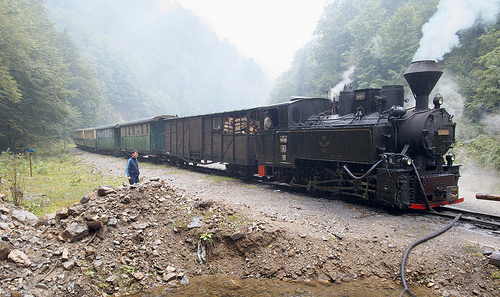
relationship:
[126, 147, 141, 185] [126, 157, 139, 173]
man wearing jacket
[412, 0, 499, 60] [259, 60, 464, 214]
steam coming from engine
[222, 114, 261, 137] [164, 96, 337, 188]
logs in car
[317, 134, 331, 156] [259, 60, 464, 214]
logo on engine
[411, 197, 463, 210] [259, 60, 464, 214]
bumper on engine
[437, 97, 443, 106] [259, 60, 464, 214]
light on engine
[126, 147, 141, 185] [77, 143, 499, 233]
man near tracks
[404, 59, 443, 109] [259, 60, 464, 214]
chimney on engine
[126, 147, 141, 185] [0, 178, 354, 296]
man near dirt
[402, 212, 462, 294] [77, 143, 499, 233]
hose coming from tracks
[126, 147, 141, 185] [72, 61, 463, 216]
man near train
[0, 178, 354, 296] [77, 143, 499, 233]
dirt near tracks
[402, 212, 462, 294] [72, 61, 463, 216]
hose leading from train